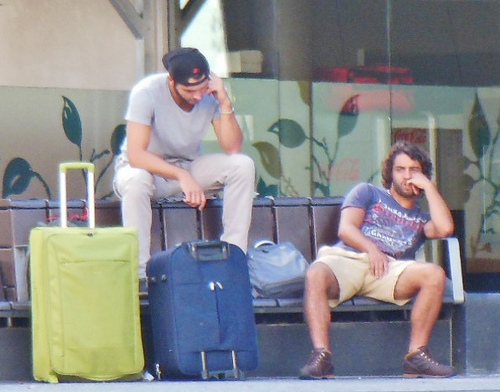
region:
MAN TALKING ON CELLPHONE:
[125, 3, 297, 228]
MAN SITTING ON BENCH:
[323, 126, 485, 278]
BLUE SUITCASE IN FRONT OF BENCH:
[136, 235, 301, 379]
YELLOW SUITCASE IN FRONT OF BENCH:
[34, 235, 137, 387]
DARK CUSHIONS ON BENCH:
[7, 219, 466, 322]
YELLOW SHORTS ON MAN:
[297, 238, 450, 320]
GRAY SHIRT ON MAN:
[327, 160, 476, 267]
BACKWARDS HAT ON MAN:
[142, 27, 229, 84]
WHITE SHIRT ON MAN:
[114, 81, 251, 175]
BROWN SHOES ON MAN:
[288, 336, 340, 389]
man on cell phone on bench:
[130, 59, 275, 229]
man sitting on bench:
[298, 124, 457, 324]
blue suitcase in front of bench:
[152, 236, 268, 385]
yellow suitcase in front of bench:
[38, 257, 170, 390]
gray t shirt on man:
[343, 186, 422, 248]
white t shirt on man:
[142, 82, 224, 176]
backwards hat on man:
[145, 37, 209, 84]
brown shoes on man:
[384, 349, 449, 390]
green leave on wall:
[33, 87, 93, 152]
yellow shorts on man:
[315, 242, 412, 312]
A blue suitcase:
[146, 237, 265, 379]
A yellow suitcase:
[23, 160, 151, 382]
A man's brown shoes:
[297, 347, 461, 385]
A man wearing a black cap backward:
[159, 44, 211, 106]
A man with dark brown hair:
[379, 140, 436, 198]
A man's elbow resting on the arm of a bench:
[401, 172, 465, 260]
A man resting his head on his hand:
[391, 163, 436, 203]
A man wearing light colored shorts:
[302, 245, 449, 347]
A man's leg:
[301, 260, 336, 346]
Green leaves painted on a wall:
[256, 80, 363, 195]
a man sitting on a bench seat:
[295, 138, 467, 377]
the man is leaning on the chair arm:
[298, 131, 478, 381]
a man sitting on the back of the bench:
[108, 40, 264, 289]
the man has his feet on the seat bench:
[112, 46, 263, 303]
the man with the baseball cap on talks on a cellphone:
[112, 39, 261, 289]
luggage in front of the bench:
[21, 158, 293, 390]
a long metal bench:
[2, 187, 481, 364]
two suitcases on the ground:
[28, 165, 264, 385]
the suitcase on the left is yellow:
[18, 146, 145, 390]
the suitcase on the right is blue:
[151, 227, 269, 383]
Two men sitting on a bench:
[106, 36, 460, 384]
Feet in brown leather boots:
[291, 342, 460, 383]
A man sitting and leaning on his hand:
[293, 134, 461, 383]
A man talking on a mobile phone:
[108, 44, 260, 251]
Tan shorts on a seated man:
[303, 239, 420, 311]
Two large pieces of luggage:
[23, 158, 263, 385]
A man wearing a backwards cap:
[158, 44, 218, 112]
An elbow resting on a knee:
[120, 143, 158, 186]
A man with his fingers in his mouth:
[378, 134, 437, 201]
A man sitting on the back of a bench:
[106, 41, 263, 303]